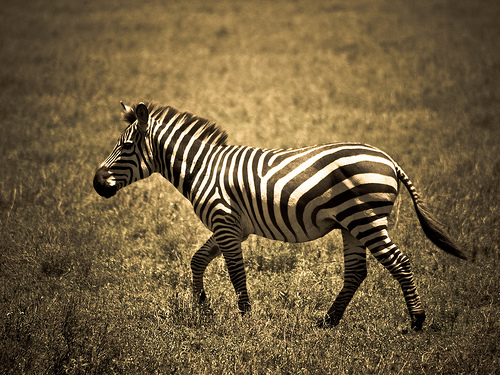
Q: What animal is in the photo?
A: A zebra.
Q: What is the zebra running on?
A: Grass.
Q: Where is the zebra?
A: On a plain.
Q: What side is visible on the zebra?
A: Left side.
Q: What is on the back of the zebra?
A: A tail.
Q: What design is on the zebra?
A: Stripes.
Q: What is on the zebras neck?
A: A mane.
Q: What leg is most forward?
A: Right leg.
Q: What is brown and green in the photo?
A: Grass.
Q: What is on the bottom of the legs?
A: Hooves.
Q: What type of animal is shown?
A: Zebra.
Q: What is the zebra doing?
A: Walking.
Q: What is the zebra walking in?
A: Grass.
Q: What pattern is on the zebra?
A: Stripes.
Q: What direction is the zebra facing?
A: Left.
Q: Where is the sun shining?
A: Behind the zebra.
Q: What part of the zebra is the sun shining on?
A: Top of the back.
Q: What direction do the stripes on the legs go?
A: Horizontal.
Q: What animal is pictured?
A: Zebra.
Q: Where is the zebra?
A: Field.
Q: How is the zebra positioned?
A: Standing.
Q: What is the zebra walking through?
A: Grass.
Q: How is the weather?
A: Sunny.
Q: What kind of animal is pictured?
A: Zebra.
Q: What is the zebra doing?
A: Running.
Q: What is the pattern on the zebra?
A: Stripes.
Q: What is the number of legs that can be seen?
A: 4.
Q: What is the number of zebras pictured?
A: 1.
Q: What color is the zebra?
A: Black and white.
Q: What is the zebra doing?
A: He is running.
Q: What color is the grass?
A: Green and brown.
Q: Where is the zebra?
A: In the plain.